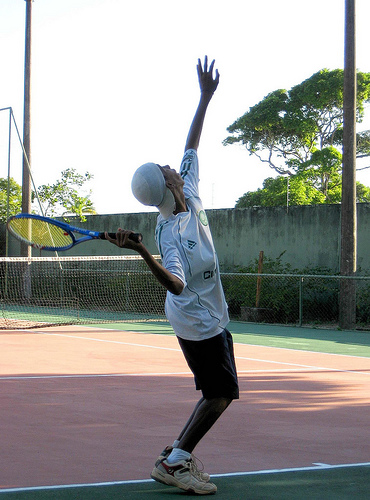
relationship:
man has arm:
[103, 52, 241, 483] [182, 57, 225, 179]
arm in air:
[182, 57, 225, 179] [107, 26, 291, 224]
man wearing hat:
[103, 52, 241, 483] [128, 160, 180, 220]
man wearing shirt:
[103, 52, 241, 483] [165, 146, 230, 341]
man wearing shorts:
[103, 52, 241, 483] [178, 328, 240, 396]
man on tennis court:
[103, 52, 241, 483] [2, 267, 367, 498]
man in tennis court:
[103, 52, 241, 483] [2, 267, 367, 498]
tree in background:
[233, 70, 366, 208] [2, 30, 367, 269]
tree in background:
[0, 164, 96, 221] [2, 30, 367, 269]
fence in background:
[2, 261, 367, 332] [2, 30, 367, 269]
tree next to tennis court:
[233, 70, 366, 208] [2, 267, 367, 498]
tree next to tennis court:
[0, 164, 96, 221] [2, 267, 367, 498]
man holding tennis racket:
[103, 52, 241, 483] [4, 210, 142, 251]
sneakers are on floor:
[151, 457, 216, 498] [2, 304, 369, 499]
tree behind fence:
[233, 70, 366, 208] [2, 261, 367, 332]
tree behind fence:
[0, 164, 96, 221] [2, 261, 367, 332]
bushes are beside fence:
[0, 259, 305, 304] [2, 261, 367, 332]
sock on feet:
[167, 446, 197, 465] [155, 454, 222, 496]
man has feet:
[103, 52, 241, 483] [155, 454, 222, 496]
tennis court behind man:
[2, 267, 367, 498] [103, 52, 241, 483]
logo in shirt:
[186, 236, 200, 250] [165, 146, 230, 341]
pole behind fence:
[21, 0, 33, 303] [2, 261, 367, 332]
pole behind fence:
[338, 0, 365, 331] [2, 261, 367, 332]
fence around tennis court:
[2, 261, 367, 332] [2, 267, 367, 498]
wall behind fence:
[0, 207, 365, 318] [2, 261, 367, 332]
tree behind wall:
[233, 70, 366, 208] [0, 207, 365, 318]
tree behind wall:
[0, 164, 96, 221] [0, 207, 365, 318]